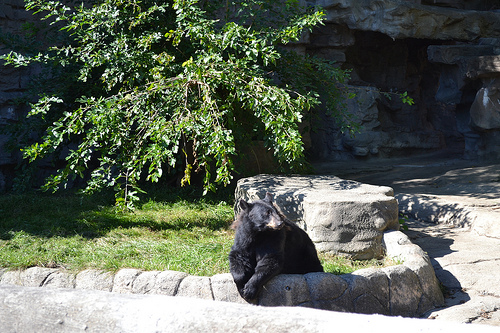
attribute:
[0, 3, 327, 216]
leaves — green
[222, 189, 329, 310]
bear — sitted, black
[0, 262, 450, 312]
fence — stoney, man made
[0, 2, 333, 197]
tree — branchy, green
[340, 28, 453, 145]
cave — dark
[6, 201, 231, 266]
grass — green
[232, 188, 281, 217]
ears — perked up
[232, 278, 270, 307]
paws — black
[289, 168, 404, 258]
stone — round